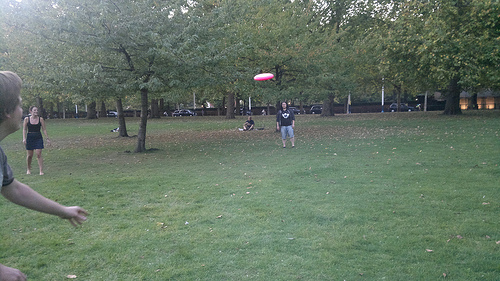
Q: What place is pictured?
A: It is a park.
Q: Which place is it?
A: It is a park.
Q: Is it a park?
A: Yes, it is a park.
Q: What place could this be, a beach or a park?
A: It is a park.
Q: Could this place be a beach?
A: No, it is a park.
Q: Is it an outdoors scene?
A: Yes, it is outdoors.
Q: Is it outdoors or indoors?
A: It is outdoors.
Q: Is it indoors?
A: No, it is outdoors.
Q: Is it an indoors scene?
A: No, it is outdoors.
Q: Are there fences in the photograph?
A: No, there are no fences.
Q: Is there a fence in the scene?
A: No, there are no fences.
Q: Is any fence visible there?
A: No, there are no fences.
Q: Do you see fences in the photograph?
A: No, there are no fences.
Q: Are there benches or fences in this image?
A: No, there are no fences or benches.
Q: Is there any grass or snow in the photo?
A: Yes, there is grass.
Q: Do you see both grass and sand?
A: No, there is grass but no sand.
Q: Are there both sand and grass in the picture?
A: No, there is grass but no sand.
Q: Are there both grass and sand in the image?
A: No, there is grass but no sand.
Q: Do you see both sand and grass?
A: No, there is grass but no sand.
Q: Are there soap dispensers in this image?
A: No, there are no soap dispensers.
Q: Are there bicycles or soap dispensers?
A: No, there are no soap dispensers or bicycles.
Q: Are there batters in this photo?
A: No, there are no batters.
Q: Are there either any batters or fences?
A: No, there are no batters or fences.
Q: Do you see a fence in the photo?
A: No, there are no fences.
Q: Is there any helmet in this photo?
A: No, there are no helmets.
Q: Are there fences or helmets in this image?
A: No, there are no helmets or fences.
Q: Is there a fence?
A: No, there are no fences.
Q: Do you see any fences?
A: No, there are no fences.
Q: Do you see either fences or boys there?
A: No, there are no fences or boys.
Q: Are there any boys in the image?
A: No, there are no boys.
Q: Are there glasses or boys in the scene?
A: No, there are no boys or glasses.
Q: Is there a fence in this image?
A: No, there are no fences.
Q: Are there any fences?
A: No, there are no fences.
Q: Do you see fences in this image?
A: No, there are no fences.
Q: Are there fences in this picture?
A: No, there are no fences.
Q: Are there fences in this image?
A: No, there are no fences.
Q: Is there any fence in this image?
A: No, there are no fences.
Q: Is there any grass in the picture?
A: Yes, there is grass.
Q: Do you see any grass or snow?
A: Yes, there is grass.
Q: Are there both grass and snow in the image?
A: No, there is grass but no snow.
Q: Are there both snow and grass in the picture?
A: No, there is grass but no snow.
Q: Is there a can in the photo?
A: No, there are no cans.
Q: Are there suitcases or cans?
A: No, there are no cans or suitcases.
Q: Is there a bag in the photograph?
A: No, there are no bags.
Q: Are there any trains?
A: No, there are no trains.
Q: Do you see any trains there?
A: No, there are no trains.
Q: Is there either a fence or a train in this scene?
A: No, there are no trains or fences.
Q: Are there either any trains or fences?
A: No, there are no trains or fences.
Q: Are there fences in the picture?
A: No, there are no fences.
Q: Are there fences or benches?
A: No, there are no fences or benches.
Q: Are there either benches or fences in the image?
A: No, there are no fences or benches.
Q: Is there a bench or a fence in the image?
A: No, there are no fences or benches.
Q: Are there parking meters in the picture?
A: No, there are no parking meters.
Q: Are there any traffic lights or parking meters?
A: No, there are no parking meters or traffic lights.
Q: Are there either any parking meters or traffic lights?
A: No, there are no parking meters or traffic lights.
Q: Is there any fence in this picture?
A: No, there are no fences.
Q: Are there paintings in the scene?
A: No, there are no paintings.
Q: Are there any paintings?
A: No, there are no paintings.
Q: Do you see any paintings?
A: No, there are no paintings.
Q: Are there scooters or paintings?
A: No, there are no paintings or scooters.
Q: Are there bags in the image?
A: No, there are no bags.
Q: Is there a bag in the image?
A: No, there are no bags.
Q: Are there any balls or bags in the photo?
A: No, there are no bags or balls.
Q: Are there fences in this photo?
A: No, there are no fences.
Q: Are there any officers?
A: No, there are no officers.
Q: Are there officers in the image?
A: No, there are no officers.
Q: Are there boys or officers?
A: No, there are no officers or boys.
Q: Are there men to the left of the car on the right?
A: Yes, there is a man to the left of the car.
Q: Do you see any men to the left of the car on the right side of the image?
A: Yes, there is a man to the left of the car.